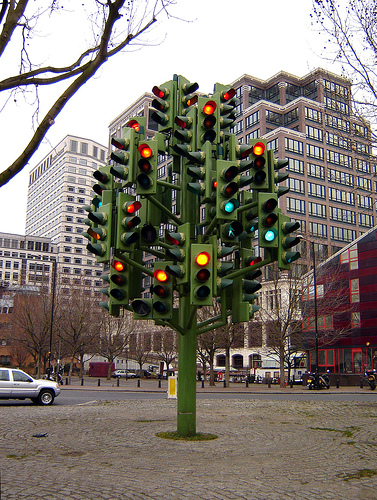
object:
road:
[0, 380, 372, 419]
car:
[0, 367, 60, 405]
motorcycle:
[307, 371, 319, 389]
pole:
[179, 290, 196, 436]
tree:
[9, 282, 132, 385]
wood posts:
[89, 361, 115, 376]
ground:
[299, 393, 375, 412]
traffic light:
[190, 243, 212, 305]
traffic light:
[217, 158, 240, 224]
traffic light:
[186, 140, 211, 203]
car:
[112, 369, 137, 379]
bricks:
[222, 455, 275, 499]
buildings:
[24, 65, 375, 383]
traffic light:
[279, 212, 300, 269]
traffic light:
[109, 252, 129, 304]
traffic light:
[250, 139, 268, 189]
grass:
[300, 389, 374, 496]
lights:
[81, 74, 298, 334]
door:
[353, 352, 361, 373]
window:
[319, 350, 325, 365]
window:
[339, 349, 342, 363]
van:
[0, 366, 60, 406]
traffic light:
[140, 146, 152, 157]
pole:
[197, 252, 209, 264]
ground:
[0, 383, 310, 481]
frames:
[318, 349, 334, 366]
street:
[1, 362, 377, 500]